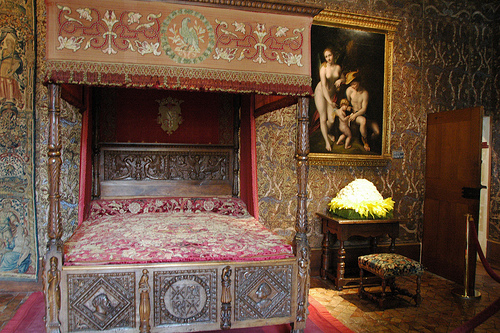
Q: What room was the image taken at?
A: It was taken at the bedroom.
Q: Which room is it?
A: It is a bedroom.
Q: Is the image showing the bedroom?
A: Yes, it is showing the bedroom.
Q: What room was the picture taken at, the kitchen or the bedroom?
A: It was taken at the bedroom.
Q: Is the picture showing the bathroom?
A: No, the picture is showing the bedroom.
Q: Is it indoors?
A: Yes, it is indoors.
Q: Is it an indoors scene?
A: Yes, it is indoors.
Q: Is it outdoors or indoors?
A: It is indoors.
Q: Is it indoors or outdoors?
A: It is indoors.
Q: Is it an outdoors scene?
A: No, it is indoors.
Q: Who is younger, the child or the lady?
A: The child is younger than the lady.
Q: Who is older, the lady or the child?
A: The lady is older than the child.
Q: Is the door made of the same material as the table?
A: Yes, both the door and the table are made of wood.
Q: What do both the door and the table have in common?
A: The material, both the door and the table are wooden.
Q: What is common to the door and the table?
A: The material, both the door and the table are wooden.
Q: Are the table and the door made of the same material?
A: Yes, both the table and the door are made of wood.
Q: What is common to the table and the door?
A: The material, both the table and the door are wooden.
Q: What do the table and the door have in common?
A: The material, both the table and the door are wooden.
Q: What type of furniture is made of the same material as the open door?
A: The table is made of the same material as the door.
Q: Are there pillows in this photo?
A: No, there are no pillows.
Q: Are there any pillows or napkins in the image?
A: No, there are no pillows or napkins.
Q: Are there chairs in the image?
A: No, there are no chairs.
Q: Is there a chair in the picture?
A: No, there are no chairs.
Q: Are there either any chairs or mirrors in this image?
A: No, there are no chairs or mirrors.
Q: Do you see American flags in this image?
A: No, there are no American flags.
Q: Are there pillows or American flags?
A: No, there are no American flags or pillows.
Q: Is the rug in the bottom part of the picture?
A: Yes, the rug is in the bottom of the image.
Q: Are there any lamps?
A: No, there are no lamps.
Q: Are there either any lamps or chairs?
A: No, there are no lamps or chairs.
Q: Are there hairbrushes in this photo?
A: No, there are no hairbrushes.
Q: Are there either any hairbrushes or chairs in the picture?
A: No, there are no hairbrushes or chairs.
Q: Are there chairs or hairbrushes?
A: No, there are no hairbrushes or chairs.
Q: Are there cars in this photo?
A: No, there are no cars.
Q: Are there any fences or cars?
A: No, there are no cars or fences.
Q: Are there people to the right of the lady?
A: Yes, there is a person to the right of the lady.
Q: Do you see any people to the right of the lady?
A: Yes, there is a person to the right of the lady.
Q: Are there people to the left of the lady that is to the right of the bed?
A: No, the person is to the right of the lady.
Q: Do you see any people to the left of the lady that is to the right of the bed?
A: No, the person is to the right of the lady.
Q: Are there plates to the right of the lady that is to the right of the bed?
A: No, there is a person to the right of the lady.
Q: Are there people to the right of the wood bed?
A: Yes, there is a person to the right of the bed.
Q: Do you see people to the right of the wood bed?
A: Yes, there is a person to the right of the bed.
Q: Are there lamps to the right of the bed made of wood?
A: No, there is a person to the right of the bed.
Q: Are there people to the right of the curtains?
A: Yes, there is a person to the right of the curtains.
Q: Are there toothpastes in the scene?
A: No, there are no toothpastes.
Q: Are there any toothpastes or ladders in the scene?
A: No, there are no toothpastes or ladders.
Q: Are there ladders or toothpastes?
A: No, there are no toothpastes or ladders.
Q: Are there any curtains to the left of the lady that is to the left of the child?
A: Yes, there are curtains to the left of the lady.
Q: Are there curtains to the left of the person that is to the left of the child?
A: Yes, there are curtains to the left of the lady.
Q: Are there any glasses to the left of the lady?
A: No, there are curtains to the left of the lady.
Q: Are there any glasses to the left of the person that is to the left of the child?
A: No, there are curtains to the left of the lady.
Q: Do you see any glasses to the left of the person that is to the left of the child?
A: No, there are curtains to the left of the lady.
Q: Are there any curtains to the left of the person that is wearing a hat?
A: Yes, there are curtains to the left of the person.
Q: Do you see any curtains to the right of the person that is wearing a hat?
A: No, the curtains are to the left of the person.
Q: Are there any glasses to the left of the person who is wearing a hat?
A: No, there are curtains to the left of the person.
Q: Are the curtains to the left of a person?
A: Yes, the curtains are to the left of a person.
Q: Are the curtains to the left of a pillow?
A: No, the curtains are to the left of a person.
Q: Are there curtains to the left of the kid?
A: Yes, there are curtains to the left of the kid.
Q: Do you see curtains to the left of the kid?
A: Yes, there are curtains to the left of the kid.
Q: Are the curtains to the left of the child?
A: Yes, the curtains are to the left of the child.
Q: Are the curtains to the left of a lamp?
A: No, the curtains are to the left of the child.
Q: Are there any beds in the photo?
A: Yes, there is a bed.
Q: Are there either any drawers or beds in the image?
A: Yes, there is a bed.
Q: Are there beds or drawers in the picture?
A: Yes, there is a bed.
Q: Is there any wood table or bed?
A: Yes, there is a wood bed.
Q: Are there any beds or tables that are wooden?
A: Yes, the bed is wooden.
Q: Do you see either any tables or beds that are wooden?
A: Yes, the bed is wooden.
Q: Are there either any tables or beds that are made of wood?
A: Yes, the bed is made of wood.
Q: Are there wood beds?
A: Yes, there is a bed that is made of wood.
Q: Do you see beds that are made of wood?
A: Yes, there is a bed that is made of wood.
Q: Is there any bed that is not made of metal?
A: Yes, there is a bed that is made of wood.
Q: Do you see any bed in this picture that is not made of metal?
A: Yes, there is a bed that is made of wood.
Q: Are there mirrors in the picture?
A: No, there are no mirrors.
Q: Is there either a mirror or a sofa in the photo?
A: No, there are no mirrors or sofas.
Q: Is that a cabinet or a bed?
A: That is a bed.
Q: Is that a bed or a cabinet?
A: That is a bed.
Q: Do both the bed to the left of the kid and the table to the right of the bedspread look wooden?
A: Yes, both the bed and the table are wooden.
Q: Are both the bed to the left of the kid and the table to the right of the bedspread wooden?
A: Yes, both the bed and the table are wooden.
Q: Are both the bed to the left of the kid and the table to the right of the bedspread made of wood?
A: Yes, both the bed and the table are made of wood.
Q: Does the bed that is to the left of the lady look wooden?
A: Yes, the bed is wooden.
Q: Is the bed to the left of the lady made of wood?
A: Yes, the bed is made of wood.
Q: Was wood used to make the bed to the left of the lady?
A: Yes, the bed is made of wood.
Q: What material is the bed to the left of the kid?
A: The bed is made of wood.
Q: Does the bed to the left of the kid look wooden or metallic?
A: The bed is wooden.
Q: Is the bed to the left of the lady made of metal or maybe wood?
A: The bed is made of wood.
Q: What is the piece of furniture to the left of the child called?
A: The piece of furniture is a bed.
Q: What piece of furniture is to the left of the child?
A: The piece of furniture is a bed.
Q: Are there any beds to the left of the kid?
A: Yes, there is a bed to the left of the kid.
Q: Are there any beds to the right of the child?
A: No, the bed is to the left of the child.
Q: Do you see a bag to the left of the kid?
A: No, there is a bed to the left of the kid.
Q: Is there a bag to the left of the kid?
A: No, there is a bed to the left of the kid.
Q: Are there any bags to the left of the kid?
A: No, there is a bed to the left of the kid.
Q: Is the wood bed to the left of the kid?
A: Yes, the bed is to the left of the kid.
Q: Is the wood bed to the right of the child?
A: No, the bed is to the left of the child.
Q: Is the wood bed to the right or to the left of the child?
A: The bed is to the left of the child.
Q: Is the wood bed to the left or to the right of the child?
A: The bed is to the left of the child.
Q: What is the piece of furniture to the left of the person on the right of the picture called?
A: The piece of furniture is a bed.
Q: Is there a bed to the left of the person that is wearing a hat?
A: Yes, there is a bed to the left of the person.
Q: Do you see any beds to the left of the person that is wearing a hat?
A: Yes, there is a bed to the left of the person.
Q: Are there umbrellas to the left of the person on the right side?
A: No, there is a bed to the left of the person.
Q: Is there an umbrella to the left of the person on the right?
A: No, there is a bed to the left of the person.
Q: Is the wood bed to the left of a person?
A: Yes, the bed is to the left of a person.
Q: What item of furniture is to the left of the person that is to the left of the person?
A: The piece of furniture is a bed.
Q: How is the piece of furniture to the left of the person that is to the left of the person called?
A: The piece of furniture is a bed.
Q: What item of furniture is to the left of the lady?
A: The piece of furniture is a bed.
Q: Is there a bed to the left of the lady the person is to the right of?
A: Yes, there is a bed to the left of the lady.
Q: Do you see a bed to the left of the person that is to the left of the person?
A: Yes, there is a bed to the left of the lady.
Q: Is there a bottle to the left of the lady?
A: No, there is a bed to the left of the lady.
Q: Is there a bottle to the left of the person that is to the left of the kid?
A: No, there is a bed to the left of the lady.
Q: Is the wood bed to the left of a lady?
A: Yes, the bed is to the left of a lady.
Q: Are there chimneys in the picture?
A: No, there are no chimneys.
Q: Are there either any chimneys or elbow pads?
A: No, there are no chimneys or elbow pads.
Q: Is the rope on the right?
A: Yes, the rope is on the right of the image.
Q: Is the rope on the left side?
A: No, the rope is on the right of the image.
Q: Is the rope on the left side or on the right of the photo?
A: The rope is on the right of the image.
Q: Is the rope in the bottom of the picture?
A: Yes, the rope is in the bottom of the image.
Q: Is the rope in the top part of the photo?
A: No, the rope is in the bottom of the image.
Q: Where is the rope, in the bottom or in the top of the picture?
A: The rope is in the bottom of the image.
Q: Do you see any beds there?
A: Yes, there is a bed.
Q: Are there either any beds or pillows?
A: Yes, there is a bed.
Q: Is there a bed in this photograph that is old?
A: Yes, there is an old bed.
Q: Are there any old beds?
A: Yes, there is an old bed.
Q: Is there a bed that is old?
A: Yes, there is a bed that is old.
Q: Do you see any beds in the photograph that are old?
A: Yes, there is a bed that is old.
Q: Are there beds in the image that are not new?
A: Yes, there is a old bed.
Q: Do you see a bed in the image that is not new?
A: Yes, there is a old bed.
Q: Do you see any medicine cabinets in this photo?
A: No, there are no medicine cabinets.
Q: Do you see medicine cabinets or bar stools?
A: No, there are no medicine cabinets or bar stools.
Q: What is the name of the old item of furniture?
A: The piece of furniture is a bed.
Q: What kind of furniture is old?
A: The furniture is a bed.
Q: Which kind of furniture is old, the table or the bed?
A: The bed is old.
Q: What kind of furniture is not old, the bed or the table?
A: The table is not old.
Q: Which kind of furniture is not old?
A: The furniture is a table.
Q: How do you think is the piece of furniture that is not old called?
A: The piece of furniture is a table.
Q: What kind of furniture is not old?
A: The furniture is a table.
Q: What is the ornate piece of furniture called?
A: The piece of furniture is a bed.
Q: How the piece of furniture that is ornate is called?
A: The piece of furniture is a bed.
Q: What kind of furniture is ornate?
A: The furniture is a bed.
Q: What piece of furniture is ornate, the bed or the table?
A: The bed is ornate.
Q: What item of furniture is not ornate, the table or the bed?
A: The table is not ornate.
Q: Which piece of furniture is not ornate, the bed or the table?
A: The table is not ornate.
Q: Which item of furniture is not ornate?
A: The piece of furniture is a table.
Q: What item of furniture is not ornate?
A: The piece of furniture is a table.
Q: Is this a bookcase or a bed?
A: This is a bed.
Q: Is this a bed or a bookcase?
A: This is a bed.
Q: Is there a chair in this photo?
A: No, there are no chairs.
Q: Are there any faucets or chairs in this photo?
A: No, there are no chairs or faucets.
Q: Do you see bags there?
A: No, there are no bags.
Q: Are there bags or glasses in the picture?
A: No, there are no bags or glasses.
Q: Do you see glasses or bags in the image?
A: No, there are no bags or glasses.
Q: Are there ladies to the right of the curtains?
A: Yes, there is a lady to the right of the curtains.